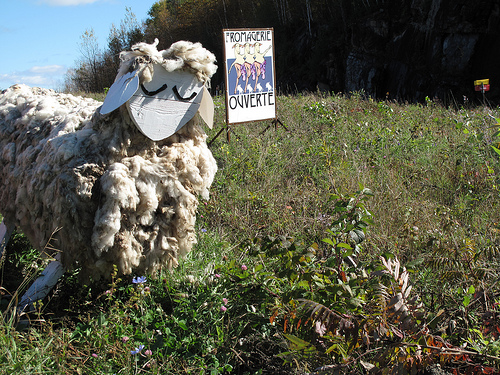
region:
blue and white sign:
[220, 37, 278, 141]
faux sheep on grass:
[14, 30, 214, 275]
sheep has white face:
[87, 65, 191, 142]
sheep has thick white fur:
[0, 87, 191, 284]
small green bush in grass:
[242, 157, 454, 374]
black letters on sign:
[217, 31, 308, 161]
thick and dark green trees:
[164, 11, 498, 102]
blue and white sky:
[2, 11, 99, 78]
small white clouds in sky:
[2, 4, 89, 78]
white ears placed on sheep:
[97, 37, 221, 138]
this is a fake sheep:
[28, 26, 398, 373]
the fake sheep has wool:
[34, 45, 219, 286]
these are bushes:
[162, 240, 442, 363]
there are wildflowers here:
[104, 291, 404, 356]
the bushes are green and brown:
[167, 209, 453, 349]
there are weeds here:
[284, 88, 491, 191]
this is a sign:
[214, 30, 326, 144]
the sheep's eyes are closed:
[110, 53, 226, 131]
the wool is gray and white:
[48, 106, 207, 264]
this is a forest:
[284, 6, 486, 113]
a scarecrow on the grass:
[0, 46, 232, 241]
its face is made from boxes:
[66, 40, 238, 153]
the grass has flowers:
[218, 231, 332, 371]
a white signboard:
[211, 20, 301, 136]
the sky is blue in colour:
[13, 0, 133, 32]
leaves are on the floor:
[248, 243, 409, 373]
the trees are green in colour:
[315, 4, 468, 83]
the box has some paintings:
[134, 63, 214, 116]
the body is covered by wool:
[26, 73, 154, 256]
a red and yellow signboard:
[453, 52, 496, 104]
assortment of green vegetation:
[278, 127, 374, 225]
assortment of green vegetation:
[387, 120, 497, 254]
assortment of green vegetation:
[368, 250, 470, 373]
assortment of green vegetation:
[242, 272, 336, 366]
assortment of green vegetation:
[120, 299, 207, 357]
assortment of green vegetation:
[19, 323, 109, 373]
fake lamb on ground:
[2, 39, 245, 319]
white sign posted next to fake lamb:
[211, 19, 293, 146]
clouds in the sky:
[11, 58, 75, 86]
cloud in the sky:
[36, 0, 117, 16]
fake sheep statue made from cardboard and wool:
[3, 38, 220, 304]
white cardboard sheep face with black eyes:
[94, 50, 221, 145]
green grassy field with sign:
[11, 81, 498, 365]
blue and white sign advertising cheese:
[209, 23, 291, 153]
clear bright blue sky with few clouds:
[4, 0, 145, 83]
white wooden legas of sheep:
[13, 246, 68, 321]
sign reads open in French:
[228, 87, 275, 109]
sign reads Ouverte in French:
[220, 25, 281, 130]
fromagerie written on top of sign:
[225, 26, 272, 42]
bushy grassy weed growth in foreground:
[146, 179, 481, 367]